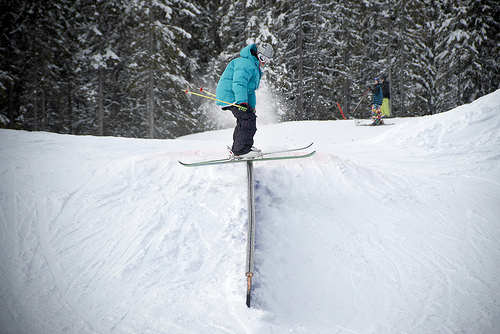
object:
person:
[216, 35, 276, 155]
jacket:
[205, 46, 261, 107]